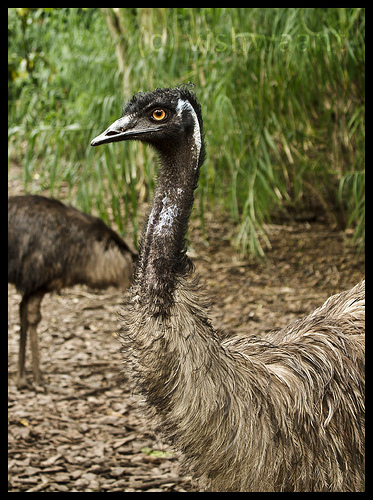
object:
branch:
[109, 4, 135, 82]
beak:
[89, 113, 144, 145]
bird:
[88, 84, 367, 493]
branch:
[253, 29, 271, 216]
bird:
[6, 187, 149, 393]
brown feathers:
[183, 281, 368, 493]